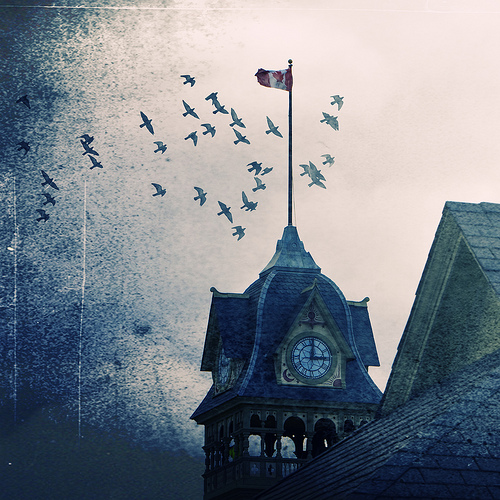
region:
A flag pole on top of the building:
[254, 55, 323, 272]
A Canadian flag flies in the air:
[258, 63, 294, 93]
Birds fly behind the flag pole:
[6, 58, 344, 236]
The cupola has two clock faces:
[179, 270, 384, 410]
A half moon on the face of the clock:
[281, 365, 296, 385]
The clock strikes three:
[292, 333, 338, 381]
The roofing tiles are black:
[370, 460, 498, 497]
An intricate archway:
[248, 407, 283, 477]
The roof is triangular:
[382, 203, 499, 412]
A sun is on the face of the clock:
[328, 366, 343, 388]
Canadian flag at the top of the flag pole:
[244, 42, 301, 97]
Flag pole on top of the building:
[245, 52, 302, 224]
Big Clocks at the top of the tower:
[195, 313, 358, 393]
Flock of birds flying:
[21, 75, 351, 254]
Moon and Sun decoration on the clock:
[272, 364, 351, 392]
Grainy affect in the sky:
[5, 8, 209, 490]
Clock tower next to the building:
[162, 235, 387, 482]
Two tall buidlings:
[185, 205, 495, 491]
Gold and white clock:
[270, 303, 360, 402]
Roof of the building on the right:
[347, 208, 494, 488]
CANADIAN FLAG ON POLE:
[253, 63, 296, 95]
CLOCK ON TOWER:
[290, 331, 335, 386]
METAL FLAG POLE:
[285, 91, 290, 228]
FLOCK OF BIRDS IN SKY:
[295, 86, 365, 203]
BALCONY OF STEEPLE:
[190, 400, 335, 470]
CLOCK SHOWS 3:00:
[290, 331, 340, 381]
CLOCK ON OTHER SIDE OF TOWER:
[210, 335, 236, 401]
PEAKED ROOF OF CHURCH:
[380, 190, 495, 375]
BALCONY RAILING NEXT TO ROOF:
[205, 455, 272, 486]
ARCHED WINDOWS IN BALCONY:
[245, 416, 264, 454]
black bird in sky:
[131, 110, 164, 135]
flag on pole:
[245, 60, 297, 94]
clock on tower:
[290, 321, 337, 377]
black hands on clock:
[304, 329, 332, 369]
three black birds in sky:
[28, 164, 62, 231]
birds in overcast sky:
[209, 84, 257, 146]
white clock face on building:
[297, 334, 335, 377]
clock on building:
[192, 226, 382, 471]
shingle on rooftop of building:
[298, 365, 494, 485]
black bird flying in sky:
[147, 172, 175, 202]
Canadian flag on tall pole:
[254, 55, 297, 223]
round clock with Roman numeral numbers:
[285, 330, 337, 383]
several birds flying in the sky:
[12, 90, 349, 239]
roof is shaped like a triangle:
[370, 199, 498, 406]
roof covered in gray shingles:
[249, 350, 494, 499]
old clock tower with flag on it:
[193, 58, 389, 498]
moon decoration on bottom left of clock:
[280, 366, 295, 383]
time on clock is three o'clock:
[290, 334, 332, 381]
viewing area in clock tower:
[188, 404, 385, 491]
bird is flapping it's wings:
[146, 178, 169, 198]